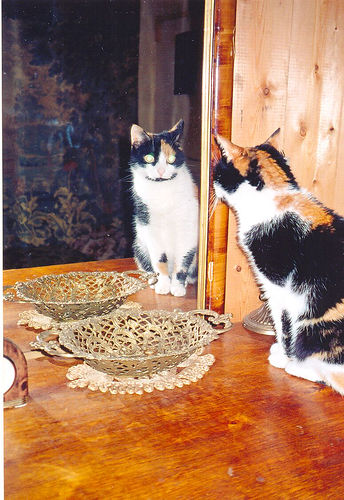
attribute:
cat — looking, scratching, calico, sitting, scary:
[205, 120, 337, 369]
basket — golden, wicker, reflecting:
[45, 279, 214, 401]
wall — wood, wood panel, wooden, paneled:
[218, 0, 343, 340]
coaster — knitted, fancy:
[58, 341, 221, 392]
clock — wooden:
[0, 309, 46, 422]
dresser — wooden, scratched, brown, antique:
[3, 299, 343, 498]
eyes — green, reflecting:
[135, 144, 180, 168]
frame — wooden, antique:
[210, 0, 237, 335]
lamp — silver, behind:
[222, 273, 304, 348]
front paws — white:
[142, 253, 204, 309]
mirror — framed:
[9, 5, 188, 328]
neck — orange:
[237, 178, 338, 238]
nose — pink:
[150, 165, 169, 175]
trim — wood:
[201, 0, 249, 323]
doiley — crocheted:
[42, 345, 230, 412]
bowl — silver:
[41, 303, 219, 373]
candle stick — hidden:
[246, 225, 282, 356]